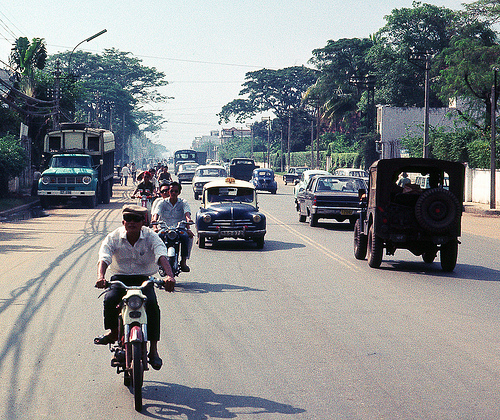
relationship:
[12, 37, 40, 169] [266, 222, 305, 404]
tree growing by street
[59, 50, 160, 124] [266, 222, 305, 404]
tree growing by street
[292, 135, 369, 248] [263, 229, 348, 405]
sedan on street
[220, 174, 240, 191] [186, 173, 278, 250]
sign on car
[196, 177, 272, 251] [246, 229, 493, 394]
cars on road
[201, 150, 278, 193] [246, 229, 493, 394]
cars on road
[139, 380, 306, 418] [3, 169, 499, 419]
shadow on ground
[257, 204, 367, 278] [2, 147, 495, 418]
line on street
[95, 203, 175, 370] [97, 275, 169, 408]
man on bike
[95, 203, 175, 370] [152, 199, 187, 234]
man wearing shirt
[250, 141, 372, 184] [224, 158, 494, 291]
hedge by road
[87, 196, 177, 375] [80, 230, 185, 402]
man on motorcycle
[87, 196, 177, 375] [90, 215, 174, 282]
man wearing shirt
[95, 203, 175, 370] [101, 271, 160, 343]
man wearing pants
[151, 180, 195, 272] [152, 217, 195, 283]
people riding a motorcycle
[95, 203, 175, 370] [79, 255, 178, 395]
man on motorcycle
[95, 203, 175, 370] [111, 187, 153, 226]
man wearing a hat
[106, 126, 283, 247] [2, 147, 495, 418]
car on street